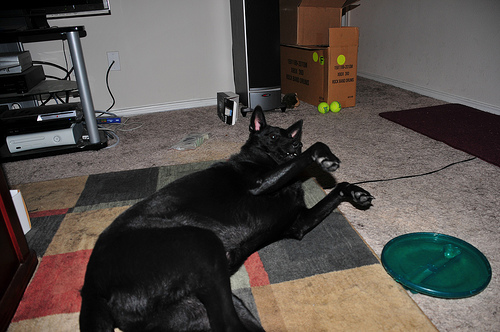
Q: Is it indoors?
A: Yes, it is indoors.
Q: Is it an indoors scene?
A: Yes, it is indoors.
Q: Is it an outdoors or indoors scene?
A: It is indoors.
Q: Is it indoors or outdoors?
A: It is indoors.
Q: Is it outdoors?
A: No, it is indoors.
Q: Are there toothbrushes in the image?
A: No, there are no toothbrushes.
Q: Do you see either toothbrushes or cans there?
A: No, there are no toothbrushes or cans.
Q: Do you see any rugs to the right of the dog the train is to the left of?
A: Yes, there is a rug to the right of the dog.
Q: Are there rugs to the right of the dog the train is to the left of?
A: Yes, there is a rug to the right of the dog.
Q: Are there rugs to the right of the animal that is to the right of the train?
A: Yes, there is a rug to the right of the dog.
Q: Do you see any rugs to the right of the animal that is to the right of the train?
A: Yes, there is a rug to the right of the dog.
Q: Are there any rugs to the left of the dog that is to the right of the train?
A: No, the rug is to the right of the dog.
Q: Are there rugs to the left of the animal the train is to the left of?
A: No, the rug is to the right of the dog.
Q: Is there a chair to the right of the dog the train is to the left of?
A: No, there is a rug to the right of the dog.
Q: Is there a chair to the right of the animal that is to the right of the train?
A: No, there is a rug to the right of the dog.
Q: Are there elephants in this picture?
A: No, there are no elephants.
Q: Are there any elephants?
A: No, there are no elephants.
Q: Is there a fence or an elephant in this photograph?
A: No, there are no elephants or fences.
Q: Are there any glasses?
A: No, there are no glasses.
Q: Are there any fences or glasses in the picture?
A: No, there are no glasses or fences.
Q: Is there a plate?
A: Yes, there is a plate.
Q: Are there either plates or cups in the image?
A: Yes, there is a plate.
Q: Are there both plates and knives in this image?
A: No, there is a plate but no knives.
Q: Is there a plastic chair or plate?
A: Yes, there is a plastic plate.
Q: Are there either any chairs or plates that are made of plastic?
A: Yes, the plate is made of plastic.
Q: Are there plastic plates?
A: Yes, there is a plate that is made of plastic.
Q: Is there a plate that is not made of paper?
A: Yes, there is a plate that is made of plastic.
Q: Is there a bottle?
A: No, there are no bottles.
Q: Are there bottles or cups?
A: No, there are no bottles or cups.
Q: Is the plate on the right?
A: Yes, the plate is on the right of the image.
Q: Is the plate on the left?
A: No, the plate is on the right of the image.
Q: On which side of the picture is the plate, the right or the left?
A: The plate is on the right of the image.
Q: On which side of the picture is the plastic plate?
A: The plate is on the right of the image.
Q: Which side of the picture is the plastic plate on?
A: The plate is on the right of the image.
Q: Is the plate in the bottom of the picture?
A: Yes, the plate is in the bottom of the image.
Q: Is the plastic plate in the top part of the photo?
A: No, the plate is in the bottom of the image.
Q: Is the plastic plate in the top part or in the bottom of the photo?
A: The plate is in the bottom of the image.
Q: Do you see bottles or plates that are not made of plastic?
A: No, there is a plate but it is made of plastic.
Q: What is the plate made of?
A: The plate is made of plastic.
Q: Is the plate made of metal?
A: No, the plate is made of plastic.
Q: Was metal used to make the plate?
A: No, the plate is made of plastic.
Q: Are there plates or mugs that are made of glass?
A: No, there is a plate but it is made of plastic.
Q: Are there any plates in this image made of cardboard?
A: No, there is a plate but it is made of plastic.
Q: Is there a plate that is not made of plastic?
A: No, there is a plate but it is made of plastic.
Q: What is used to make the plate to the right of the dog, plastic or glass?
A: The plate is made of plastic.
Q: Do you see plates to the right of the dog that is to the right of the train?
A: Yes, there is a plate to the right of the dog.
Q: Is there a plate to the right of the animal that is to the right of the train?
A: Yes, there is a plate to the right of the dog.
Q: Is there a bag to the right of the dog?
A: No, there is a plate to the right of the dog.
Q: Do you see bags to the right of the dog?
A: No, there is a plate to the right of the dog.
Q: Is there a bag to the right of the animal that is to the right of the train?
A: No, there is a plate to the right of the dog.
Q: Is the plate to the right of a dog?
A: Yes, the plate is to the right of a dog.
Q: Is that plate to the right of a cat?
A: No, the plate is to the right of a dog.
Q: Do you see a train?
A: Yes, there is a train.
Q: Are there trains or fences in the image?
A: Yes, there is a train.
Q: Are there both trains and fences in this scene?
A: No, there is a train but no fences.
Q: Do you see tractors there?
A: No, there are no tractors.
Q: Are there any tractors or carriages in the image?
A: No, there are no tractors or carriages.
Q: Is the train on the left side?
A: Yes, the train is on the left of the image.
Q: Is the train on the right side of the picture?
A: No, the train is on the left of the image.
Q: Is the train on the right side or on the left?
A: The train is on the left of the image.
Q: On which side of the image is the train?
A: The train is on the left of the image.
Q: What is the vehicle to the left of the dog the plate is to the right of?
A: The vehicle is a train.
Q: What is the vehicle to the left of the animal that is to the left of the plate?
A: The vehicle is a train.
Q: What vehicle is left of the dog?
A: The vehicle is a train.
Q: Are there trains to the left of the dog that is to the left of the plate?
A: Yes, there is a train to the left of the dog.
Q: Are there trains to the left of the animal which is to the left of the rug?
A: Yes, there is a train to the left of the dog.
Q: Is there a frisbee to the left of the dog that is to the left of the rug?
A: No, there is a train to the left of the dog.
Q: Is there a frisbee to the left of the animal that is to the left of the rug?
A: No, there is a train to the left of the dog.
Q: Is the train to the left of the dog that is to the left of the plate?
A: Yes, the train is to the left of the dog.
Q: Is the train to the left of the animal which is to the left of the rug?
A: Yes, the train is to the left of the dog.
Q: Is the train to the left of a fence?
A: No, the train is to the left of the dog.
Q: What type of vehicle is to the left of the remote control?
A: The vehicle is a train.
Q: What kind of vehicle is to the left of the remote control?
A: The vehicle is a train.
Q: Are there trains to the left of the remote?
A: Yes, there is a train to the left of the remote.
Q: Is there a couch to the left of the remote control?
A: No, there is a train to the left of the remote control.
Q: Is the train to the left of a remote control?
A: Yes, the train is to the left of a remote control.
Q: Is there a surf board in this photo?
A: No, there are no surfboards.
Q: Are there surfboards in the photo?
A: No, there are no surfboards.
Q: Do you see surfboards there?
A: No, there are no surfboards.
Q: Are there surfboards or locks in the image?
A: No, there are no surfboards or locks.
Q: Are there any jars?
A: No, there are no jars.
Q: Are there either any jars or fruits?
A: No, there are no jars or fruits.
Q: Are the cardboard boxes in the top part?
A: Yes, the boxes are in the top of the image.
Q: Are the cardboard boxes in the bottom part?
A: No, the boxes are in the top of the image.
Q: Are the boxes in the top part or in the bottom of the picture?
A: The boxes are in the top of the image.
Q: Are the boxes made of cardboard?
A: Yes, the boxes are made of cardboard.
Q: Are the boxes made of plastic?
A: No, the boxes are made of cardboard.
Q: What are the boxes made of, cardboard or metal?
A: The boxes are made of cardboard.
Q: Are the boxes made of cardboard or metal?
A: The boxes are made of cardboard.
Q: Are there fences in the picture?
A: No, there are no fences.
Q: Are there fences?
A: No, there are no fences.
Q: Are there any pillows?
A: No, there are no pillows.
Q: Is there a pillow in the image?
A: No, there are no pillows.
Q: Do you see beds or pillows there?
A: No, there are no pillows or beds.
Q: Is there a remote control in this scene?
A: Yes, there is a remote control.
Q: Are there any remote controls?
A: Yes, there is a remote control.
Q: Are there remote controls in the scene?
A: Yes, there is a remote control.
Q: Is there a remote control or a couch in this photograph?
A: Yes, there is a remote control.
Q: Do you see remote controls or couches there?
A: Yes, there is a remote control.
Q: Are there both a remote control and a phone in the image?
A: No, there is a remote control but no phones.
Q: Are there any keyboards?
A: No, there are no keyboards.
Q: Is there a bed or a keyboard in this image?
A: No, there are no keyboards or beds.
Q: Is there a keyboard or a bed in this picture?
A: No, there are no keyboards or beds.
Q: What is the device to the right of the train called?
A: The device is a remote control.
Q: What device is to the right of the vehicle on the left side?
A: The device is a remote control.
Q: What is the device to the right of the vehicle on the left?
A: The device is a remote control.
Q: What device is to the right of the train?
A: The device is a remote control.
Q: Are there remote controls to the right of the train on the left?
A: Yes, there is a remote control to the right of the train.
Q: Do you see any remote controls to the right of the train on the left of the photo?
A: Yes, there is a remote control to the right of the train.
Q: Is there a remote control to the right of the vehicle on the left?
A: Yes, there is a remote control to the right of the train.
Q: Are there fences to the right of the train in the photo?
A: No, there is a remote control to the right of the train.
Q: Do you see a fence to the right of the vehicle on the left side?
A: No, there is a remote control to the right of the train.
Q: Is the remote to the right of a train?
A: Yes, the remote is to the right of a train.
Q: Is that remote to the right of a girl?
A: No, the remote is to the right of a train.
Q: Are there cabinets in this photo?
A: No, there are no cabinets.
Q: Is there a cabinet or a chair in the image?
A: No, there are no cabinets or chairs.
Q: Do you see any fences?
A: No, there are no fences.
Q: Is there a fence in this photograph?
A: No, there are no fences.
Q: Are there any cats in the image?
A: No, there are no cats.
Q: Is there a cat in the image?
A: No, there are no cats.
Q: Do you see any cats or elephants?
A: No, there are no cats or elephants.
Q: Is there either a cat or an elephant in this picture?
A: No, there are no cats or elephants.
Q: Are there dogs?
A: Yes, there is a dog.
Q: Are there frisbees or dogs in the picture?
A: Yes, there is a dog.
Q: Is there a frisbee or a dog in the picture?
A: Yes, there is a dog.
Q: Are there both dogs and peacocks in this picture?
A: No, there is a dog but no peacocks.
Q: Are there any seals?
A: No, there are no seals.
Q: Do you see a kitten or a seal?
A: No, there are no seals or kittens.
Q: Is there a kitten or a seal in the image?
A: No, there are no seals or kittens.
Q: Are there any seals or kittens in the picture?
A: No, there are no seals or kittens.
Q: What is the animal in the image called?
A: The animal is a dog.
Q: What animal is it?
A: The animal is a dog.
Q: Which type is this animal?
A: This is a dog.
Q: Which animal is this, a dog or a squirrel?
A: This is a dog.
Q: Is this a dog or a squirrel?
A: This is a dog.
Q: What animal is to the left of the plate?
A: The animal is a dog.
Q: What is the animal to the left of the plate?
A: The animal is a dog.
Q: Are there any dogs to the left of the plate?
A: Yes, there is a dog to the left of the plate.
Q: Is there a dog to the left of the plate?
A: Yes, there is a dog to the left of the plate.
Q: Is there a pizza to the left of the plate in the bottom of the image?
A: No, there is a dog to the left of the plate.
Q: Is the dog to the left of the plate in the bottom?
A: Yes, the dog is to the left of the plate.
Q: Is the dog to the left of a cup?
A: No, the dog is to the left of the plate.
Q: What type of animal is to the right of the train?
A: The animal is a dog.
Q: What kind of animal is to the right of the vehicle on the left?
A: The animal is a dog.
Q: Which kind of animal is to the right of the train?
A: The animal is a dog.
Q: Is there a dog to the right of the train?
A: Yes, there is a dog to the right of the train.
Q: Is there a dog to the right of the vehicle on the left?
A: Yes, there is a dog to the right of the train.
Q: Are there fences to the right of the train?
A: No, there is a dog to the right of the train.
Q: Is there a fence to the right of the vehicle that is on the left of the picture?
A: No, there is a dog to the right of the train.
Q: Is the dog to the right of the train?
A: Yes, the dog is to the right of the train.